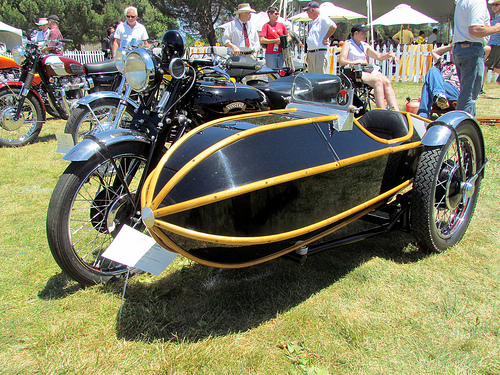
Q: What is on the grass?
A: A motorcycle.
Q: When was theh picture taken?
A: Daytime.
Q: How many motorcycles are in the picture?
A: Three.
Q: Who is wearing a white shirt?
A: A man wearing sunglasses.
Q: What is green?
A: The grass.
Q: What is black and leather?
A: Motorbike seat.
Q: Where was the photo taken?
A: At model car showing.